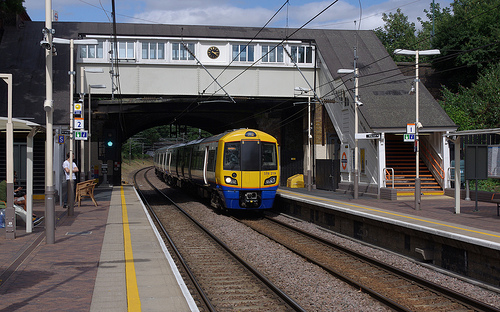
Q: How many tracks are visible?
A: Two.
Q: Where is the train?
A: On the track closest to platform.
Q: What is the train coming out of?
A: A tunnel.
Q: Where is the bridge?
A: Over the train.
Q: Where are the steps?
A: Beyond, the lampposts, to the right.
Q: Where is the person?
A: On the left side of the tracks.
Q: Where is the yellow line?
A: Between the person and the train, on the left side.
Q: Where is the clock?
A: In the center of the bridge.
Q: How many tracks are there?
A: Two.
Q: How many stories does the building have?
A: Two.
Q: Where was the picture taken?
A: At the train station.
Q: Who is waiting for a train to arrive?
A: A man in white shirt.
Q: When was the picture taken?
A: During daytime.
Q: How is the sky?
A: Cloudy.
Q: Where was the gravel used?
A: Next to the train tracks.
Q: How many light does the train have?
A: Two.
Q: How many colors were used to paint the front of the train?
A: Two.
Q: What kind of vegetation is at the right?
A: Trees.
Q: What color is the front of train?
A: Yellow and blue.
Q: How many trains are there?
A: One.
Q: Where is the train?
A: On the tracks.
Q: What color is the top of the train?
A: Yellow.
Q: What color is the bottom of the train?
A: Blue.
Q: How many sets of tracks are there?
A: Two.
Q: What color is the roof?
A: Grey.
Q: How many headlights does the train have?
A: Two.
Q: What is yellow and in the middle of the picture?
A: A train.